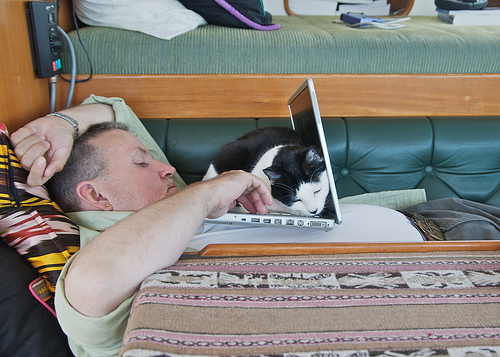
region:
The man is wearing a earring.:
[73, 180, 116, 215]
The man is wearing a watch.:
[44, 107, 85, 138]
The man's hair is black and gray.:
[40, 116, 177, 216]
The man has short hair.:
[46, 120, 177, 216]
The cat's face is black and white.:
[253, 141, 331, 218]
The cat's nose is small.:
[308, 205, 318, 214]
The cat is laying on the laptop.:
[200, 122, 328, 215]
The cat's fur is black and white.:
[201, 122, 339, 219]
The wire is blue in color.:
[58, 29, 81, 111]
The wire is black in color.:
[70, 16, 97, 71]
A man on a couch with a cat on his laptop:
[0, 65, 361, 348]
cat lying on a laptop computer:
[168, 70, 350, 236]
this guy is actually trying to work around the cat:
[4, 71, 350, 238]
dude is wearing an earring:
[95, 196, 119, 213]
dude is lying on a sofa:
[7, 99, 499, 254]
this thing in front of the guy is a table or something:
[121, 238, 498, 353]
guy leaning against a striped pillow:
[0, 116, 86, 313]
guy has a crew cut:
[42, 104, 184, 213]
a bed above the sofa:
[56, 3, 498, 118]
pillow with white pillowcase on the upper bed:
[63, 0, 214, 42]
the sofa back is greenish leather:
[143, 108, 498, 210]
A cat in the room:
[240, 135, 314, 196]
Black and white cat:
[228, 118, 330, 230]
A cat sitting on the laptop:
[239, 112, 317, 204]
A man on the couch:
[80, 139, 205, 266]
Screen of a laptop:
[254, 81, 341, 131]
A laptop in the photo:
[230, 93, 344, 243]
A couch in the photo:
[370, 110, 436, 196]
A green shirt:
[64, 312, 101, 342]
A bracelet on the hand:
[43, 105, 76, 135]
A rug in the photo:
[247, 256, 360, 321]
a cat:
[236, 141, 329, 209]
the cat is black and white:
[261, 136, 304, 173]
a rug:
[262, 257, 369, 345]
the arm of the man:
[105, 227, 161, 264]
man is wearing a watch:
[57, 108, 78, 124]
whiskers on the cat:
[323, 201, 336, 217]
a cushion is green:
[318, 35, 496, 65]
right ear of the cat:
[259, 164, 278, 185]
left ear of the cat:
[299, 148, 321, 160]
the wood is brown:
[380, 77, 471, 110]